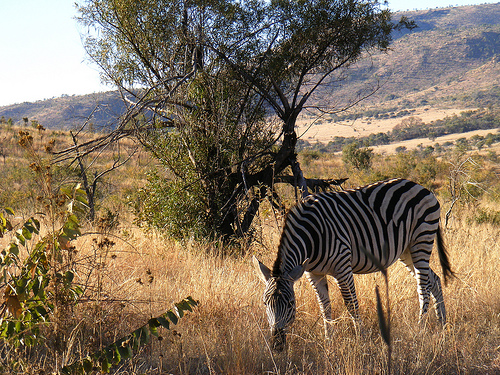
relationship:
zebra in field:
[261, 185, 469, 325] [18, 132, 497, 358]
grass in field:
[127, 235, 249, 333] [18, 132, 497, 358]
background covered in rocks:
[0, 0, 500, 138] [376, 66, 446, 92]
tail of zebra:
[433, 227, 462, 279] [261, 185, 469, 325]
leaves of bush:
[56, 229, 75, 246] [5, 188, 156, 349]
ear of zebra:
[252, 255, 276, 288] [261, 185, 469, 325]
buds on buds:
[374, 299, 395, 341] [357, 247, 400, 374]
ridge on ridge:
[389, 2, 500, 27] [389, 2, 500, 27]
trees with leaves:
[101, 7, 332, 207] [182, 44, 273, 129]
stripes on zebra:
[315, 221, 390, 255] [261, 185, 469, 325]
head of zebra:
[257, 284, 295, 343] [261, 185, 469, 325]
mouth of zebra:
[269, 332, 287, 352] [261, 185, 469, 325]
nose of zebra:
[265, 328, 284, 346] [261, 185, 469, 325]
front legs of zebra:
[310, 278, 384, 354] [261, 185, 469, 325]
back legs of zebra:
[407, 245, 450, 314] [261, 185, 469, 325]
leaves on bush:
[56, 229, 75, 246] [5, 188, 156, 349]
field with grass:
[18, 132, 497, 358] [127, 235, 249, 333]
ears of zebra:
[244, 254, 320, 280] [261, 185, 469, 325]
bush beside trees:
[5, 188, 156, 349] [101, 7, 332, 207]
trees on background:
[326, 102, 405, 117] [0, 0, 500, 138]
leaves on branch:
[182, 44, 273, 129] [201, 38, 268, 81]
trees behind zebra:
[101, 7, 332, 207] [261, 185, 469, 325]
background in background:
[0, 0, 500, 138] [0, 0, 500, 138]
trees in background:
[326, 102, 405, 117] [0, 0, 500, 138]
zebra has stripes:
[261, 185, 469, 325] [315, 221, 390, 255]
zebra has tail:
[261, 185, 469, 325] [433, 227, 462, 279]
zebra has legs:
[261, 185, 469, 325] [305, 287, 489, 352]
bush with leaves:
[5, 188, 156, 349] [56, 229, 75, 246]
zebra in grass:
[261, 185, 469, 325] [127, 235, 249, 333]